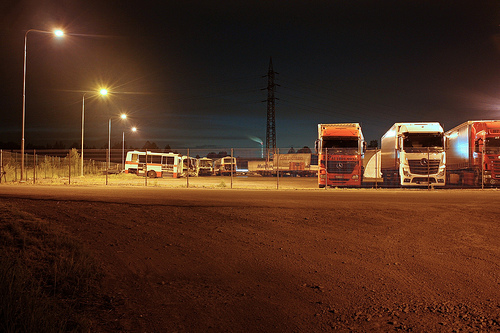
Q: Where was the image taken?
A: It was taken at the parking lot.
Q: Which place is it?
A: It is a parking lot.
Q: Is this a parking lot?
A: Yes, it is a parking lot.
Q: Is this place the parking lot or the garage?
A: It is the parking lot.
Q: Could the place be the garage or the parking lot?
A: It is the parking lot.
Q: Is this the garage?
A: No, it is the parking lot.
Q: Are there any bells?
A: No, there are no bells.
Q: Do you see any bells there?
A: No, there are no bells.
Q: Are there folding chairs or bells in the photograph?
A: No, there are no bells or folding chairs.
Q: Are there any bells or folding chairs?
A: No, there are no bells or folding chairs.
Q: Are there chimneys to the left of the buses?
A: Yes, there is a chimney to the left of the buses.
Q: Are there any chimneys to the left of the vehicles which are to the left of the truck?
A: Yes, there is a chimney to the left of the buses.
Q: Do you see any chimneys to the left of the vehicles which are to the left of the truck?
A: Yes, there is a chimney to the left of the buses.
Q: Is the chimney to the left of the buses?
A: Yes, the chimney is to the left of the buses.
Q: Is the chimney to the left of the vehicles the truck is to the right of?
A: Yes, the chimney is to the left of the buses.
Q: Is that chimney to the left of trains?
A: No, the chimney is to the left of the buses.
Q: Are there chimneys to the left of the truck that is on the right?
A: Yes, there is a chimney to the left of the truck.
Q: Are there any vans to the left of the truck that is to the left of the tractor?
A: No, there is a chimney to the left of the truck.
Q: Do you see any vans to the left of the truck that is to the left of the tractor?
A: No, there is a chimney to the left of the truck.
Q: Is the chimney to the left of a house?
A: No, the chimney is to the left of the truck.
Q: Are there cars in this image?
A: No, there are no cars.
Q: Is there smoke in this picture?
A: Yes, there is smoke.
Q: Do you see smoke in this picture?
A: Yes, there is smoke.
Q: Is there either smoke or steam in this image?
A: Yes, there is smoke.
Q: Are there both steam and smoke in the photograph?
A: No, there is smoke but no steam.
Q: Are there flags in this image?
A: No, there are no flags.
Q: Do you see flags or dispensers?
A: No, there are no flags or dispensers.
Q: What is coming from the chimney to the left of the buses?
A: The smoke is coming from the chimney.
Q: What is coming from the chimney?
A: The smoke is coming from the chimney.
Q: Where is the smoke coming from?
A: The smoke is coming from the chimney.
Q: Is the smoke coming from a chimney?
A: Yes, the smoke is coming from a chimney.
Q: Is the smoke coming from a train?
A: No, the smoke is coming from a chimney.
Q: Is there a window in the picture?
A: Yes, there are windows.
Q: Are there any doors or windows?
A: Yes, there are windows.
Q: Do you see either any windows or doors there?
A: Yes, there are windows.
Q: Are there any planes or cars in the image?
A: No, there are no cars or planes.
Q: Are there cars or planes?
A: No, there are no cars or planes.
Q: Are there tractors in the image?
A: Yes, there is a tractor.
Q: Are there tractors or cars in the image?
A: Yes, there is a tractor.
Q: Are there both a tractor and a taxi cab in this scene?
A: No, there is a tractor but no taxis.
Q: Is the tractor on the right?
A: Yes, the tractor is on the right of the image.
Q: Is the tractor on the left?
A: No, the tractor is on the right of the image.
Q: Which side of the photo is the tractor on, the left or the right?
A: The tractor is on the right of the image.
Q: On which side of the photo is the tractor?
A: The tractor is on the right of the image.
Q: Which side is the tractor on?
A: The tractor is on the right of the image.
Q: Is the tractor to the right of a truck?
A: Yes, the tractor is to the right of a truck.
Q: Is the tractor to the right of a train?
A: No, the tractor is to the right of a truck.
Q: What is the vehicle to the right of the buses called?
A: The vehicle is a tractor.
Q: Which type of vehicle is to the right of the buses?
A: The vehicle is a tractor.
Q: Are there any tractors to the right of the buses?
A: Yes, there is a tractor to the right of the buses.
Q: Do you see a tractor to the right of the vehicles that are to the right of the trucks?
A: Yes, there is a tractor to the right of the buses.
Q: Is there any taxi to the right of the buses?
A: No, there is a tractor to the right of the buses.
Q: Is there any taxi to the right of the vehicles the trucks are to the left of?
A: No, there is a tractor to the right of the buses.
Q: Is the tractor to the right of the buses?
A: Yes, the tractor is to the right of the buses.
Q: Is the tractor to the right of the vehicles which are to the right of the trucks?
A: Yes, the tractor is to the right of the buses.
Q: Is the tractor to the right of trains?
A: No, the tractor is to the right of the buses.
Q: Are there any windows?
A: Yes, there is a window.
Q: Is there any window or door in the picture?
A: Yes, there is a window.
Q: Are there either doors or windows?
A: Yes, there is a window.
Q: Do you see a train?
A: No, there are no trains.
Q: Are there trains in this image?
A: No, there are no trains.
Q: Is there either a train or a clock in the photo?
A: No, there are no trains or clocks.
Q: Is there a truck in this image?
A: Yes, there are trucks.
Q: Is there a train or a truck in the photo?
A: Yes, there are trucks.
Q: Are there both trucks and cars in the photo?
A: No, there are trucks but no cars.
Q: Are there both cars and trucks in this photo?
A: No, there are trucks but no cars.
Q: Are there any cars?
A: No, there are no cars.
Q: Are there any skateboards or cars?
A: No, there are no cars or skateboards.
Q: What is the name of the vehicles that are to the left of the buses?
A: The vehicles are trucks.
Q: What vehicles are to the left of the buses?
A: The vehicles are trucks.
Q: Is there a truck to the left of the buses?
A: Yes, there are trucks to the left of the buses.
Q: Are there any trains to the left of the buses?
A: No, there are trucks to the left of the buses.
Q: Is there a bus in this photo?
A: Yes, there are buses.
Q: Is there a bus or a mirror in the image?
A: Yes, there are buses.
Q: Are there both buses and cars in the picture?
A: No, there are buses but no cars.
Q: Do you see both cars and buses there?
A: No, there are buses but no cars.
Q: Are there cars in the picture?
A: No, there are no cars.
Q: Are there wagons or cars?
A: No, there are no cars or wagons.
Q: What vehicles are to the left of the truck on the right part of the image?
A: The vehicles are buses.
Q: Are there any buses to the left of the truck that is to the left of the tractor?
A: Yes, there are buses to the left of the truck.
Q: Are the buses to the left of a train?
A: No, the buses are to the left of the truck.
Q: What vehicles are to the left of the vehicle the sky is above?
A: The vehicles are buses.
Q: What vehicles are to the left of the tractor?
A: The vehicles are buses.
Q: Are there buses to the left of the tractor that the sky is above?
A: Yes, there are buses to the left of the tractor.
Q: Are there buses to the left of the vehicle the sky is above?
A: Yes, there are buses to the left of the tractor.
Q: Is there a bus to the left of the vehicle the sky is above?
A: Yes, there are buses to the left of the tractor.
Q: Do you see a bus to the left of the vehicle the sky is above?
A: Yes, there are buses to the left of the tractor.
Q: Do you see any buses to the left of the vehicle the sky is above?
A: Yes, there are buses to the left of the tractor.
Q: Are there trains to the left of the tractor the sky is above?
A: No, there are buses to the left of the tractor.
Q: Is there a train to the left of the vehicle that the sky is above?
A: No, there are buses to the left of the tractor.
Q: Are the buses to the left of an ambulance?
A: No, the buses are to the left of a tractor.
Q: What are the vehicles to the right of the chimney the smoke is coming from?
A: The vehicles are buses.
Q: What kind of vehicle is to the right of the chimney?
A: The vehicles are buses.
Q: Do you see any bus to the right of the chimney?
A: Yes, there are buses to the right of the chimney.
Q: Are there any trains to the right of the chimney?
A: No, there are buses to the right of the chimney.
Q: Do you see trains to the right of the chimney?
A: No, there are buses to the right of the chimney.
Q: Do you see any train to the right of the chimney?
A: No, there are buses to the right of the chimney.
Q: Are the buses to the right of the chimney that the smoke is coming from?
A: Yes, the buses are to the right of the chimney.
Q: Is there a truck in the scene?
A: Yes, there is a truck.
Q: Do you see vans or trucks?
A: Yes, there is a truck.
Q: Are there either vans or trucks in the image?
A: Yes, there is a truck.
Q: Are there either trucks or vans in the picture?
A: Yes, there is a truck.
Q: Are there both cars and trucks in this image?
A: No, there is a truck but no cars.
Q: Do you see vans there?
A: No, there are no vans.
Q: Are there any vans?
A: No, there are no vans.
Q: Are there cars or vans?
A: No, there are no vans or cars.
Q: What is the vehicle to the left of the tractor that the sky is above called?
A: The vehicle is a truck.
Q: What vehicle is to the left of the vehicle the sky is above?
A: The vehicle is a truck.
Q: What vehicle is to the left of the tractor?
A: The vehicle is a truck.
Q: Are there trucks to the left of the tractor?
A: Yes, there is a truck to the left of the tractor.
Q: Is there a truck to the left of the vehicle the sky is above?
A: Yes, there is a truck to the left of the tractor.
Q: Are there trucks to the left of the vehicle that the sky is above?
A: Yes, there is a truck to the left of the tractor.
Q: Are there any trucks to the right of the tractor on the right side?
A: No, the truck is to the left of the tractor.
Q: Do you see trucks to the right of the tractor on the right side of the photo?
A: No, the truck is to the left of the tractor.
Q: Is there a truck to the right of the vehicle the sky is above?
A: No, the truck is to the left of the tractor.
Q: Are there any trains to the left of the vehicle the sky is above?
A: No, there is a truck to the left of the tractor.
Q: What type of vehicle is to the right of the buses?
A: The vehicle is a truck.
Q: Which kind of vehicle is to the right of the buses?
A: The vehicle is a truck.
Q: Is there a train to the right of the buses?
A: No, there is a truck to the right of the buses.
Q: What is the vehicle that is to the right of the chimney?
A: The vehicle is a truck.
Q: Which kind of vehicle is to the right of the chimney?
A: The vehicle is a truck.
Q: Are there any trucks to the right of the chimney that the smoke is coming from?
A: Yes, there is a truck to the right of the chimney.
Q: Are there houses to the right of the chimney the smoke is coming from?
A: No, there is a truck to the right of the chimney.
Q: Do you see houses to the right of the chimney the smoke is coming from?
A: No, there is a truck to the right of the chimney.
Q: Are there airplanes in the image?
A: No, there are no airplanes.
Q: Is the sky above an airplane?
A: No, the sky is above the tractor.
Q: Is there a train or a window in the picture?
A: Yes, there is a window.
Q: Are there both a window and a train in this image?
A: No, there is a window but no trains.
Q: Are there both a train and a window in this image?
A: No, there is a window but no trains.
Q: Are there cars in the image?
A: No, there are no cars.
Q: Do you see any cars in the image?
A: No, there are no cars.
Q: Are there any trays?
A: No, there are no trays.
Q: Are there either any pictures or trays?
A: No, there are no trays or pictures.